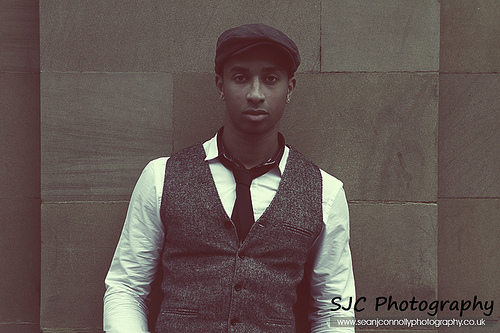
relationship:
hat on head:
[212, 22, 302, 74] [212, 24, 301, 132]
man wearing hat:
[101, 20, 362, 332] [212, 22, 302, 74]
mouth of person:
[242, 106, 269, 120] [101, 20, 362, 332]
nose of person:
[249, 76, 267, 102] [101, 20, 362, 332]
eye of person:
[263, 73, 279, 87] [101, 20, 362, 332]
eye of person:
[230, 73, 248, 85] [101, 20, 362, 332]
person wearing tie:
[101, 20, 362, 332] [218, 155, 275, 239]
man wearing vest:
[101, 20, 362, 332] [158, 144, 326, 328]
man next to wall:
[101, 20, 362, 332] [39, 1, 499, 331]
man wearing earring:
[101, 20, 362, 332] [287, 96, 293, 104]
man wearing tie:
[101, 20, 362, 332] [218, 155, 275, 239]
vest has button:
[158, 144, 326, 328] [237, 248, 247, 260]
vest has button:
[158, 144, 326, 328] [232, 280, 246, 293]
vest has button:
[158, 144, 326, 328] [229, 315, 240, 327]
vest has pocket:
[158, 144, 326, 328] [280, 220, 314, 238]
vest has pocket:
[158, 144, 326, 328] [157, 304, 199, 318]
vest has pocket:
[158, 144, 326, 328] [264, 311, 298, 328]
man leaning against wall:
[101, 20, 362, 332] [39, 1, 499, 331]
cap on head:
[212, 22, 302, 74] [212, 24, 301, 132]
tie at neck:
[218, 155, 275, 239] [219, 132, 285, 163]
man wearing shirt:
[101, 20, 362, 332] [103, 136, 361, 332]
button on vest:
[237, 248, 247, 260] [158, 144, 326, 328]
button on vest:
[232, 280, 246, 293] [158, 144, 326, 328]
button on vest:
[229, 315, 240, 327] [158, 144, 326, 328]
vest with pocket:
[158, 144, 326, 328] [280, 220, 314, 238]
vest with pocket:
[158, 144, 326, 328] [157, 304, 199, 318]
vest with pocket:
[158, 144, 326, 328] [264, 311, 298, 328]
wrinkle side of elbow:
[111, 273, 153, 287] [100, 273, 153, 302]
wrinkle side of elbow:
[108, 290, 147, 299] [100, 273, 153, 302]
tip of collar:
[204, 154, 212, 165] [205, 133, 220, 163]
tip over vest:
[204, 154, 212, 165] [158, 144, 326, 328]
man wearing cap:
[101, 20, 362, 332] [212, 22, 302, 74]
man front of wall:
[101, 20, 362, 332] [39, 1, 499, 331]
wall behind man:
[39, 1, 499, 331] [101, 20, 362, 332]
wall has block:
[39, 1, 499, 331] [42, 73, 177, 201]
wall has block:
[39, 1, 499, 331] [171, 71, 440, 202]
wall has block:
[39, 1, 499, 331] [41, 200, 129, 327]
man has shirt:
[101, 20, 362, 332] [103, 136, 361, 332]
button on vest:
[222, 216, 236, 230] [158, 144, 326, 328]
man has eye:
[101, 20, 362, 332] [263, 73, 279, 87]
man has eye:
[101, 20, 362, 332] [230, 73, 248, 85]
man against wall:
[101, 20, 362, 332] [39, 1, 499, 331]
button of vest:
[232, 280, 246, 293] [158, 144, 326, 328]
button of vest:
[229, 315, 240, 327] [158, 144, 326, 328]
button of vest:
[237, 248, 247, 260] [158, 144, 326, 328]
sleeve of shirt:
[101, 161, 162, 331] [103, 136, 361, 332]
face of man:
[222, 54, 288, 133] [101, 20, 362, 332]